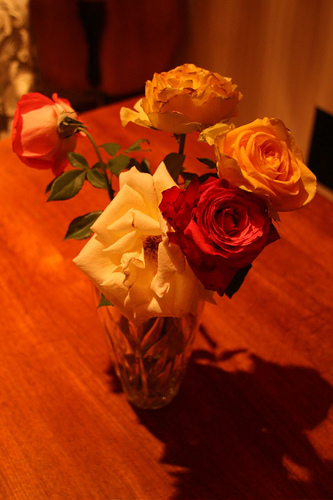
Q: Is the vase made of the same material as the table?
A: No, the vase is made of glass and the table is made of wood.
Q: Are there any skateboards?
A: No, there are no skateboards.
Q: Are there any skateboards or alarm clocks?
A: No, there are no skateboards or alarm clocks.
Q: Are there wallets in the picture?
A: No, there are no wallets.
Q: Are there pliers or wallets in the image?
A: No, there are no wallets or pliers.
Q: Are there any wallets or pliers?
A: No, there are no wallets or pliers.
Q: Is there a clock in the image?
A: No, there are no clocks.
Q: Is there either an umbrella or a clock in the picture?
A: No, there are no clocks or umbrellas.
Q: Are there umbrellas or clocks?
A: No, there are no clocks or umbrellas.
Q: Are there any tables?
A: Yes, there is a table.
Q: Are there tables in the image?
A: Yes, there is a table.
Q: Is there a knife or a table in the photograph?
A: Yes, there is a table.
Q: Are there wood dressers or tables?
A: Yes, there is a wood table.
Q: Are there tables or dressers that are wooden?
A: Yes, the table is wooden.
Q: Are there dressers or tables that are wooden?
A: Yes, the table is wooden.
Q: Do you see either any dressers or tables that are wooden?
A: Yes, the table is wooden.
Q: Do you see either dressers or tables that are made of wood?
A: Yes, the table is made of wood.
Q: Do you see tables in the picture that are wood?
A: Yes, there is a wood table.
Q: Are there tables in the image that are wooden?
A: Yes, there is a table that is wooden.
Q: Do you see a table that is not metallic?
A: Yes, there is a wooden table.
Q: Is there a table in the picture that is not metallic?
A: Yes, there is a wooden table.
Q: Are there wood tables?
A: Yes, there is a table that is made of wood.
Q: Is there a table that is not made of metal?
A: Yes, there is a table that is made of wood.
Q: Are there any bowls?
A: No, there are no bowls.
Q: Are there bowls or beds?
A: No, there are no bowls or beds.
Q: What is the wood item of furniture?
A: The piece of furniture is a table.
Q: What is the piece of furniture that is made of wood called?
A: The piece of furniture is a table.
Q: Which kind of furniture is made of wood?
A: The furniture is a table.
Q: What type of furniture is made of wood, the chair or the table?
A: The table is made of wood.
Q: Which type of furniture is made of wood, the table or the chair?
A: The table is made of wood.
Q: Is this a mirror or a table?
A: This is a table.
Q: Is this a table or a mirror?
A: This is a table.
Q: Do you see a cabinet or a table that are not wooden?
A: No, there is a table but it is wooden.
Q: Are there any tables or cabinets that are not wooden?
A: No, there is a table but it is wooden.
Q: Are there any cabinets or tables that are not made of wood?
A: No, there is a table but it is made of wood.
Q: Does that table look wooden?
A: Yes, the table is wooden.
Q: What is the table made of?
A: The table is made of wood.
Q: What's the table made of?
A: The table is made of wood.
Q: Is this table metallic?
A: No, the table is wooden.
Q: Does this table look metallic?
A: No, the table is wooden.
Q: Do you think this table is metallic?
A: No, the table is wooden.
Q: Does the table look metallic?
A: No, the table is wooden.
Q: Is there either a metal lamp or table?
A: No, there is a table but it is wooden.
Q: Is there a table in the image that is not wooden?
A: No, there is a table but it is wooden.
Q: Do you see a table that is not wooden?
A: No, there is a table but it is wooden.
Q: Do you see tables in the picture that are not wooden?
A: No, there is a table but it is wooden.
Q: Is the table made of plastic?
A: No, the table is made of wood.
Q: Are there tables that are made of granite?
A: No, there is a table but it is made of wood.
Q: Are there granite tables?
A: No, there is a table but it is made of wood.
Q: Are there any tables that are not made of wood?
A: No, there is a table but it is made of wood.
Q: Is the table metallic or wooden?
A: The table is wooden.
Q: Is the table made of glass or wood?
A: The table is made of wood.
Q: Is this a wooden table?
A: Yes, this is a wooden table.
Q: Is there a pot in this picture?
A: No, there are no pots.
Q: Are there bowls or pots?
A: No, there are no pots or bowls.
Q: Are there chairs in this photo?
A: Yes, there is a chair.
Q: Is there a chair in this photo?
A: Yes, there is a chair.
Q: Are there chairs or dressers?
A: Yes, there is a chair.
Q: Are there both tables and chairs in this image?
A: Yes, there are both a chair and a table.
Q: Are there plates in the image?
A: No, there are no plates.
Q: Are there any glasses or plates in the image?
A: No, there are no plates or glasses.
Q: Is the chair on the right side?
A: Yes, the chair is on the right of the image.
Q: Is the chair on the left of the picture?
A: No, the chair is on the right of the image.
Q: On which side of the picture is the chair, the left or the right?
A: The chair is on the right of the image.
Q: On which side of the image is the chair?
A: The chair is on the right of the image.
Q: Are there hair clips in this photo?
A: No, there are no hair clips.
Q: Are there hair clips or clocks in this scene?
A: No, there are no hair clips or clocks.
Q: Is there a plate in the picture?
A: No, there are no plates.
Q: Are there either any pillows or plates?
A: No, there are no plates or pillows.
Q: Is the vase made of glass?
A: Yes, the vase is made of glass.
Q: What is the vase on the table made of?
A: The vase is made of glass.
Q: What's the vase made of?
A: The vase is made of glass.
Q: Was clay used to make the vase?
A: No, the vase is made of glass.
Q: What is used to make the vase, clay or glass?
A: The vase is made of glass.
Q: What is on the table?
A: The vase is on the table.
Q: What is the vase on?
A: The vase is on the table.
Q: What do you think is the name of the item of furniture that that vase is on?
A: The piece of furniture is a table.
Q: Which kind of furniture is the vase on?
A: The vase is on the table.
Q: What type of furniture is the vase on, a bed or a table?
A: The vase is on a table.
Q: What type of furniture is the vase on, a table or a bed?
A: The vase is on a table.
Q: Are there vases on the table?
A: Yes, there is a vase on the table.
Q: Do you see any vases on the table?
A: Yes, there is a vase on the table.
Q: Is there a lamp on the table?
A: No, there is a vase on the table.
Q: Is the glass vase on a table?
A: Yes, the vase is on a table.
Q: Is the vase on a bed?
A: No, the vase is on a table.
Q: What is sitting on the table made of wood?
A: The vase is sitting on the table.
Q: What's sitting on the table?
A: The vase is sitting on the table.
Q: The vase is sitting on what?
A: The vase is sitting on the table.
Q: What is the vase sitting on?
A: The vase is sitting on the table.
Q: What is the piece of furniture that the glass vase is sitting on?
A: The piece of furniture is a table.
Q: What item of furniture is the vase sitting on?
A: The vase is sitting on the table.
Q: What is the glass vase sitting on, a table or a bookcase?
A: The vase is sitting on a table.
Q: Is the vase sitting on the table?
A: Yes, the vase is sitting on the table.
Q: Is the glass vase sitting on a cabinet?
A: No, the vase is sitting on the table.